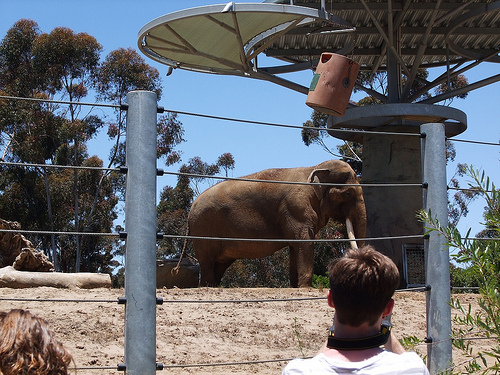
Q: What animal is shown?
A: Elephant.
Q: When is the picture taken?
A: Daytime.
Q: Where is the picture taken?
A: Zoo.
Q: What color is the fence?
A: Grey.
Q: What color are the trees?
A: Green.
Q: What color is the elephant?
A: Brown.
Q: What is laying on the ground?
A: Log.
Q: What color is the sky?
A: Blue.